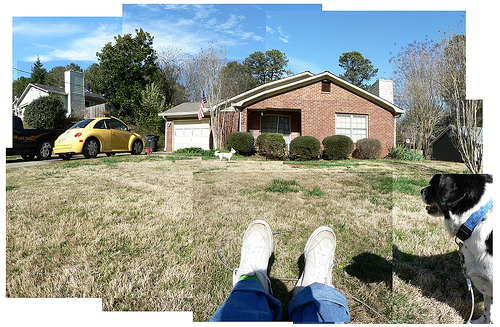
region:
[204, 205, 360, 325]
Feet of the photographer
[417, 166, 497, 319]
Dog in the yard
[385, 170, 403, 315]
Mistakes made by panoramic camera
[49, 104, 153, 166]
Modern Volkswagen Beetle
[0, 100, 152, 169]
Vehicles sitting in the driveway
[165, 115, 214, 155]
Overhead garage door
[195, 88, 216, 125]
American flag attached to house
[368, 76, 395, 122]
Chimney for a fireplace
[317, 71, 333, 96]
Air vents for the attic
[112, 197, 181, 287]
Water starved front lawn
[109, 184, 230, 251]
dried grass of lawn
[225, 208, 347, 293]
white shoes on grass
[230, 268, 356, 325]
cuffs of blue jeans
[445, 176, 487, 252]
dog with blue collar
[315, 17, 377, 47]
blue of daytime sky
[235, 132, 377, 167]
bushes in front of house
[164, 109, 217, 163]
white door on garage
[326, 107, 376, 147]
window in brick wall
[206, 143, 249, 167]
white dog on lawn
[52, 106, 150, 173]
yellow car in driveway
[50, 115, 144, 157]
yellow Volkswagen Beetle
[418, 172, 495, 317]
black and white dog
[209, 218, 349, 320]
legs with rolled up denim and white tennis shoes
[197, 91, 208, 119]
American flag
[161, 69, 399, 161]
house with brick exterior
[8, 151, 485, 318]
dried yellow grass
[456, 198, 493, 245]
blue collar on dog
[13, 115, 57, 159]
part of smaller black pickup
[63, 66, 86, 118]
large white chimney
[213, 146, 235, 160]
small white dog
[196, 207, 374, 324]
Person sitting in the grass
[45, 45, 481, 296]
Pictures pieced together to form a scene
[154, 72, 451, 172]
House in the background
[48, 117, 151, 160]
Yellow Beetle parked in driveway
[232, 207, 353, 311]
White tennis shoes on feet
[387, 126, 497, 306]
Black and white dog sitting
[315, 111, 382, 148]
Large window on the side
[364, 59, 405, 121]
Chimney on top of the house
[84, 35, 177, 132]
Large tree in the field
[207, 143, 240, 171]
White dog in front of house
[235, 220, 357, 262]
Person wearing white shoes.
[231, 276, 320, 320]
Person wearing blue pants.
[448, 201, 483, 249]
Dog wearing blue collar.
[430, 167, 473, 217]
Dog has black ear.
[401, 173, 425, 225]
Dog has black nose.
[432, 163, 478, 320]
dog is white and black.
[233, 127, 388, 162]
Green bushes in front of house.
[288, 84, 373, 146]
Red brick house behind bushes.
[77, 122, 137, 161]
Yellow VW car parked in driveway.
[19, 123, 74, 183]
Black truck parked in driveway.